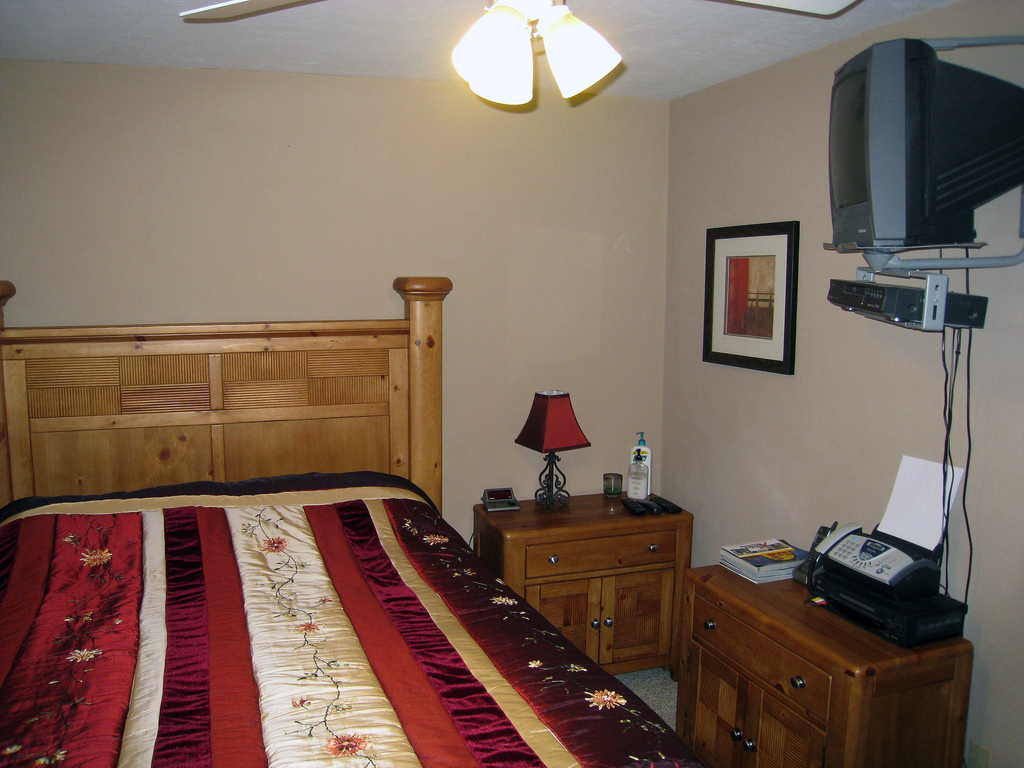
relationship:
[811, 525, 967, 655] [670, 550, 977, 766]
printer on table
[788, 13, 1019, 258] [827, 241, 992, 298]
television on stand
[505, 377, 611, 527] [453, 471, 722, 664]
lamp on table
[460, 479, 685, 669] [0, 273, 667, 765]
table near bed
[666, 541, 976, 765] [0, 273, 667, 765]
cabinet near bed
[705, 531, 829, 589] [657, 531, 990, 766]
books on cabinet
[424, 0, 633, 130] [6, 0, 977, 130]
light in ceiling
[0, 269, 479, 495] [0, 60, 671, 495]
headboard on wall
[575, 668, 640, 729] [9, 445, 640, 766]
flower on bed spread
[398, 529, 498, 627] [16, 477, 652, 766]
flowers on bed spread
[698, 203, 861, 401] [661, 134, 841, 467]
picture on wall